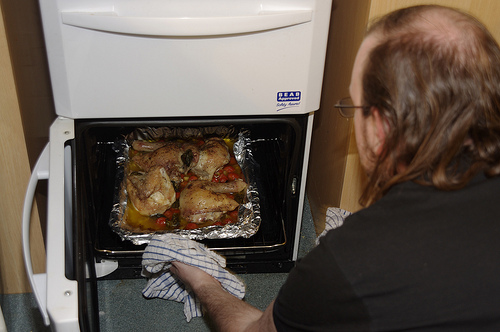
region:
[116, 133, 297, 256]
Food in a oven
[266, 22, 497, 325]
The man has a shirt on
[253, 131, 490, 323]
The man has a black shirt on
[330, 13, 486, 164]
The man has glasses on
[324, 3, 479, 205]
The man has eye glasses on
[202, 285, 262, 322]
the arm is hairy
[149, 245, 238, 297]
hand under the towel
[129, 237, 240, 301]
towel touching the pan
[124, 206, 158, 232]
juice in the pan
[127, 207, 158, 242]
the liquid is brown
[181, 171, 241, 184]
the carrots are cooked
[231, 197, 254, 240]
the foil is shiny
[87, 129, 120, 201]
the stove is dark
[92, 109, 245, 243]
chicken is in oven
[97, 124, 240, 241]
red tomatoes with chicken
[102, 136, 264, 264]
chicken on aluminum foil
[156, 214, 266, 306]
blue and white towel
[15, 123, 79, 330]
white door on oven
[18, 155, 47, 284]
white handle on door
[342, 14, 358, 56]
brown wall behind oven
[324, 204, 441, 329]
man has black shirt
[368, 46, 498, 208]
man has brown hair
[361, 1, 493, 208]
man has long hair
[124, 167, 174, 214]
a golden brown chicken in an oven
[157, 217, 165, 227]
a tomato in a roasting tray in an oven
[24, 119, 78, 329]
the white exterior on an oven door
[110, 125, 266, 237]
a tray of chicken roasting in an oven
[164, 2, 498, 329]
a man in a black shirt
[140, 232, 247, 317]
a white dish towel in a mans hand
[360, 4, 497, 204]
brown hair on a mans head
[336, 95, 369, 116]
a pair of glasses on a mans face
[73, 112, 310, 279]
the black interior of an oven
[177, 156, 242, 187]
vegetables on the meat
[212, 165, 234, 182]
the carrots are orange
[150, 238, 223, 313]
the towel is striped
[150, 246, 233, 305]
towel on the hand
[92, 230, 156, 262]
the rack is silver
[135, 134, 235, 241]
meat on the foil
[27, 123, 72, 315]
the door is white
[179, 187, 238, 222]
piece of baked chicken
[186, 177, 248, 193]
piece of baked chicken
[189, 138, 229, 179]
piece of baked chicken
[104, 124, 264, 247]
chicken on foil covered pan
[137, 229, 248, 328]
blue and white checkered towel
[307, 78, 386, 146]
glasses on the man's face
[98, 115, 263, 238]
food in the oven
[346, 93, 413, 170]
ear of the man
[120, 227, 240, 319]
cloth held by the man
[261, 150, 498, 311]
black shirt on man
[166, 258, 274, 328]
arm of the man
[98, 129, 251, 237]
many food items in oven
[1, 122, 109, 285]
door of the oven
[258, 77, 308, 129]
logo on the oven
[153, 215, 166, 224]
carrot on food pan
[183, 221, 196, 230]
carrot on food pan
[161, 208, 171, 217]
carrot on food pan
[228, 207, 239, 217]
carrot on food pan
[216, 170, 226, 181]
carrot on food pan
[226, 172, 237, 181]
carrot on food pan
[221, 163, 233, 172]
carrot on food pan